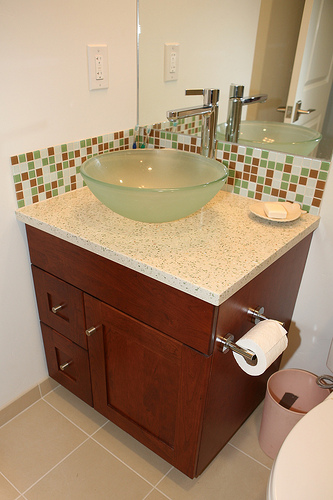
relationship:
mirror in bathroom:
[137, 0, 332, 163] [5, 5, 332, 499]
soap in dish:
[267, 201, 288, 220] [242, 200, 302, 224]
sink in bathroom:
[77, 148, 230, 225] [5, 5, 332, 499]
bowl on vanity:
[77, 148, 230, 225] [16, 164, 319, 480]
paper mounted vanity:
[232, 318, 290, 380] [16, 164, 319, 480]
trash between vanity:
[257, 362, 331, 465] [16, 164, 319, 480]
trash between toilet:
[257, 362, 331, 465] [263, 385, 331, 499]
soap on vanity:
[267, 201, 288, 220] [16, 164, 319, 480]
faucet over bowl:
[166, 87, 220, 157] [77, 148, 230, 225]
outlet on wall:
[86, 43, 111, 94] [3, 3, 134, 204]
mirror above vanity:
[137, 0, 332, 163] [16, 164, 319, 480]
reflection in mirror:
[278, 3, 331, 157] [137, 0, 332, 163]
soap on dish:
[267, 201, 288, 220] [242, 200, 302, 224]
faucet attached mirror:
[166, 87, 220, 157] [137, 0, 332, 163]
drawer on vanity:
[33, 266, 88, 351] [16, 164, 319, 480]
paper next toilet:
[232, 318, 290, 380] [263, 385, 331, 499]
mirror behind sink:
[137, 0, 332, 163] [77, 148, 230, 225]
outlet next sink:
[86, 43, 111, 94] [77, 148, 230, 225]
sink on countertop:
[77, 148, 230, 225] [15, 149, 320, 306]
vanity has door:
[16, 164, 319, 480] [84, 294, 206, 479]